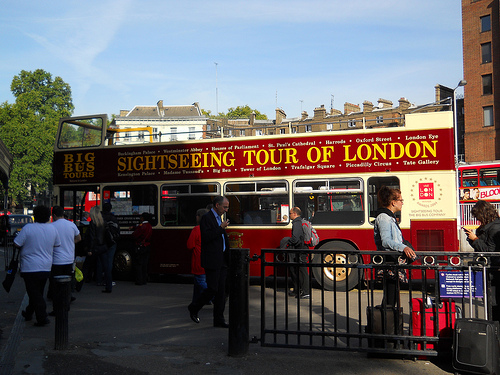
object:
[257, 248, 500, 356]
gate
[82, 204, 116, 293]
woman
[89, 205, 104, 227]
blond hair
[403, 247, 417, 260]
hand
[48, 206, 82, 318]
man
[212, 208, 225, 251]
shirt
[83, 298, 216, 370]
floor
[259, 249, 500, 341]
fence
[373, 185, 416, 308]
woman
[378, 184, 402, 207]
hair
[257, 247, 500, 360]
baracade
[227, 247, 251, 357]
black pole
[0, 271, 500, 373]
ground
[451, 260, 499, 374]
suitcase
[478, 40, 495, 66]
window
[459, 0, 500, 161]
building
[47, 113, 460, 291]
bus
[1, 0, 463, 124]
sky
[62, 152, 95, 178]
print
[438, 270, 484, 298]
sign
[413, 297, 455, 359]
bag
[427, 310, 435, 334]
red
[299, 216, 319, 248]
backpack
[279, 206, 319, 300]
man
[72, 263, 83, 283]
hat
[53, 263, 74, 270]
loop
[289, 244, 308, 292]
pants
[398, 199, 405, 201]
glasses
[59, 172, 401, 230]
window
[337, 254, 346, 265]
rust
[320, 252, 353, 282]
hubcap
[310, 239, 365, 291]
tire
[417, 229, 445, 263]
vent